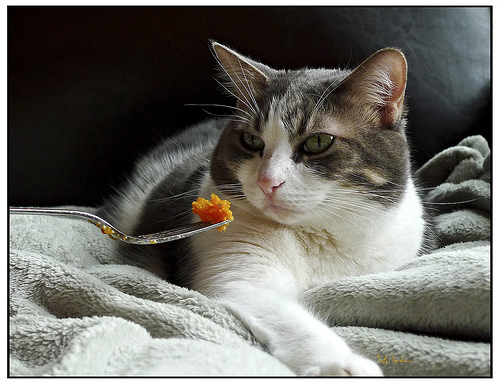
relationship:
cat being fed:
[106, 42, 427, 382] [180, 171, 305, 241]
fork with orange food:
[10, 192, 237, 248] [184, 187, 239, 241]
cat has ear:
[106, 42, 427, 382] [321, 40, 412, 125]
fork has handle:
[10, 192, 237, 248] [9, 200, 99, 228]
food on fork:
[184, 187, 239, 241] [10, 192, 237, 248]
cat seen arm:
[106, 42, 427, 382] [201, 260, 381, 383]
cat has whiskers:
[106, 42, 427, 382] [141, 180, 469, 245]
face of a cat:
[228, 66, 391, 228] [106, 42, 427, 382]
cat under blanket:
[106, 42, 427, 382] [12, 162, 497, 384]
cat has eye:
[106, 42, 427, 382] [231, 130, 267, 164]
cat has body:
[106, 42, 427, 382] [106, 105, 240, 282]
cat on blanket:
[106, 42, 427, 382] [12, 162, 497, 384]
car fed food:
[106, 42, 427, 382] [184, 187, 239, 241]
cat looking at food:
[106, 42, 427, 382] [184, 187, 239, 241]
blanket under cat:
[12, 162, 497, 384] [106, 42, 427, 382]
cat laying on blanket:
[106, 42, 427, 382] [12, 162, 497, 384]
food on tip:
[184, 187, 239, 241] [187, 215, 233, 236]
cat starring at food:
[106, 42, 427, 382] [184, 187, 239, 241]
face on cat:
[199, 34, 420, 236] [106, 42, 427, 382]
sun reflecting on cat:
[106, 42, 427, 382] [106, 42, 427, 382]